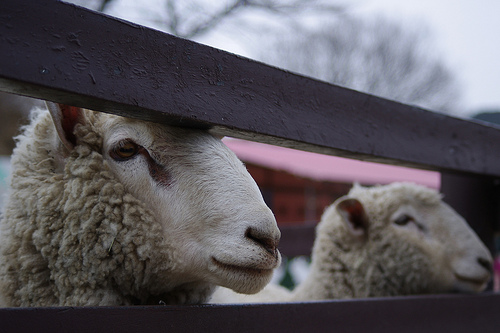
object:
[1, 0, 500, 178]
fence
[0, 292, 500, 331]
board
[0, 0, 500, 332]
fence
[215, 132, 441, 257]
building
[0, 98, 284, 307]
sheep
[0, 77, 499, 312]
two sheep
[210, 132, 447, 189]
roof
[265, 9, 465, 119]
tree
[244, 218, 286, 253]
nose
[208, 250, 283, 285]
mouth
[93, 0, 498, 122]
frees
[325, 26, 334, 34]
leaves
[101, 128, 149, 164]
eye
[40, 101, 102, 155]
ear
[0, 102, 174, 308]
wool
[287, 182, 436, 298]
wool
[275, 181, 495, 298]
sheep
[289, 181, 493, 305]
sheep background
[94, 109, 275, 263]
face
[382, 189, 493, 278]
face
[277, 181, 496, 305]
sheep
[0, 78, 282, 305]
heads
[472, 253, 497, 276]
sheep's nose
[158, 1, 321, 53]
trees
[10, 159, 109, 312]
fur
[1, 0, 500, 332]
background